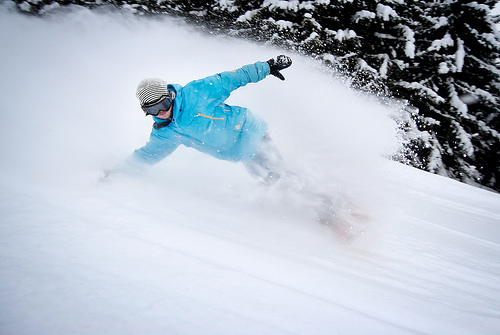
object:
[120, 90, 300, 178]
jacket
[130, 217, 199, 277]
snow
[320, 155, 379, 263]
snowboard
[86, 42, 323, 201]
woman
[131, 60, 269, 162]
coat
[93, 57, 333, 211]
player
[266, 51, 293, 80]
black mitten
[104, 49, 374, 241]
man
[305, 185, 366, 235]
ski boots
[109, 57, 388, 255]
person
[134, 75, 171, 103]
hat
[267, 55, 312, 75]
glove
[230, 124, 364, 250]
ski pants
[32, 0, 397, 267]
woman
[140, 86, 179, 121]
goggles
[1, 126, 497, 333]
snow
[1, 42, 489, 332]
mountainside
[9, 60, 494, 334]
hillside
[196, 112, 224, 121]
zipper